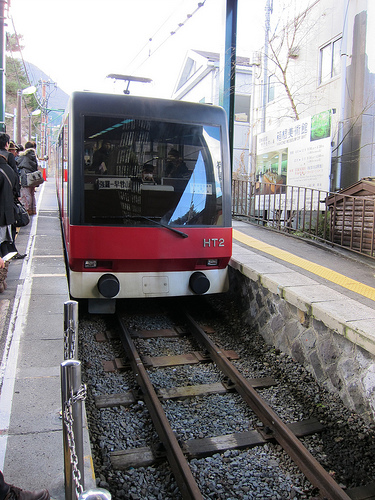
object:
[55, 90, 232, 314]
train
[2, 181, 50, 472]
lines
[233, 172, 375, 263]
railing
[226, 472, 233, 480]
small rock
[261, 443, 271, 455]
small rock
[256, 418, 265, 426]
small rock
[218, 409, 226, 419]
small rock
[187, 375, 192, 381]
small rock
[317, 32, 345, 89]
window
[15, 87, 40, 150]
light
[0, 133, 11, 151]
head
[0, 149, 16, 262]
man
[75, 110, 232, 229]
window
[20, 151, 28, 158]
shoulder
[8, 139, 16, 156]
person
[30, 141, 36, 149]
person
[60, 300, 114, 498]
metal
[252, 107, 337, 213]
sign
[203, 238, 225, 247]
letters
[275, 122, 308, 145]
letters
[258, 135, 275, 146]
letters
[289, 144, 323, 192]
letters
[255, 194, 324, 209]
letters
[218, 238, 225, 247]
number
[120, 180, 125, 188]
number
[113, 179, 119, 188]
number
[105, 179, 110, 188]
number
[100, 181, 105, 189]
number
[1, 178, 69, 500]
platform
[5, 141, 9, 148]
ear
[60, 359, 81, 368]
ring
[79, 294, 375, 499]
railway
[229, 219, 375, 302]
line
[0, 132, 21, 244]
people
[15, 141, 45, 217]
lady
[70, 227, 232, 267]
red part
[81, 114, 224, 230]
windshield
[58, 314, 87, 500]
chain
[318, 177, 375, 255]
house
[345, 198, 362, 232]
brown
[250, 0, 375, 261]
building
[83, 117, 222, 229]
reflections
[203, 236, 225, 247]
written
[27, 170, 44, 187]
big bag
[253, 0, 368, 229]
wall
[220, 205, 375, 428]
platform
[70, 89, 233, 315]
head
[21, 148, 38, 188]
back